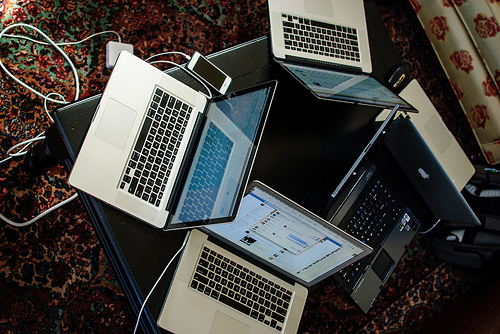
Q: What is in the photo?
A: Laptops.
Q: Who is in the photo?
A: Noone.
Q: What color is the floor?
A: Brown.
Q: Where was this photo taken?
A: At an office.